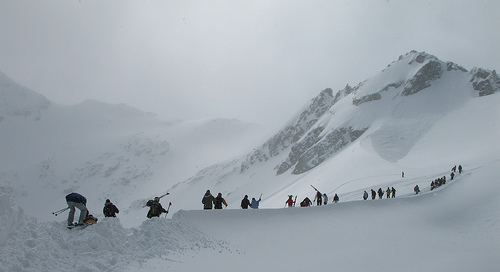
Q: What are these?
A: Skiers.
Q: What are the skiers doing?
A: Walking up the mountain.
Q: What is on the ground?
A: Snow.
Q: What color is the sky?
A: Gray.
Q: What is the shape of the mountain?
A: Pointy.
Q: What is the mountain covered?
A: Snow.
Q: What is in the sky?
A: Clouds.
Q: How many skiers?
A: 22.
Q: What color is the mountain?
A: Black and white.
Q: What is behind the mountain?
A: More mountains.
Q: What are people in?
A: Line.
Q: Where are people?
A: In snow.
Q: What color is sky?
A: Gray.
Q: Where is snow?
A: On mountain.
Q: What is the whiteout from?
A: Fog.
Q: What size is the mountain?
A: Small.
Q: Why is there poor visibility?
A: Snow.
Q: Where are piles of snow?
A: Snow bank.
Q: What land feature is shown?
A: Mountain.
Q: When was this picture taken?
A: Outside, during the daytime.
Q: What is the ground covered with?
A: Snow.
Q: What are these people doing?
A: Walking.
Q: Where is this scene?
A: On top of a mountain ridge.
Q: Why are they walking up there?
A: To ski down.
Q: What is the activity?
A: Extreme skiing.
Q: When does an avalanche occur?
A: When the snow is unsteady and starts to break loose.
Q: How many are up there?
A: More than 20.